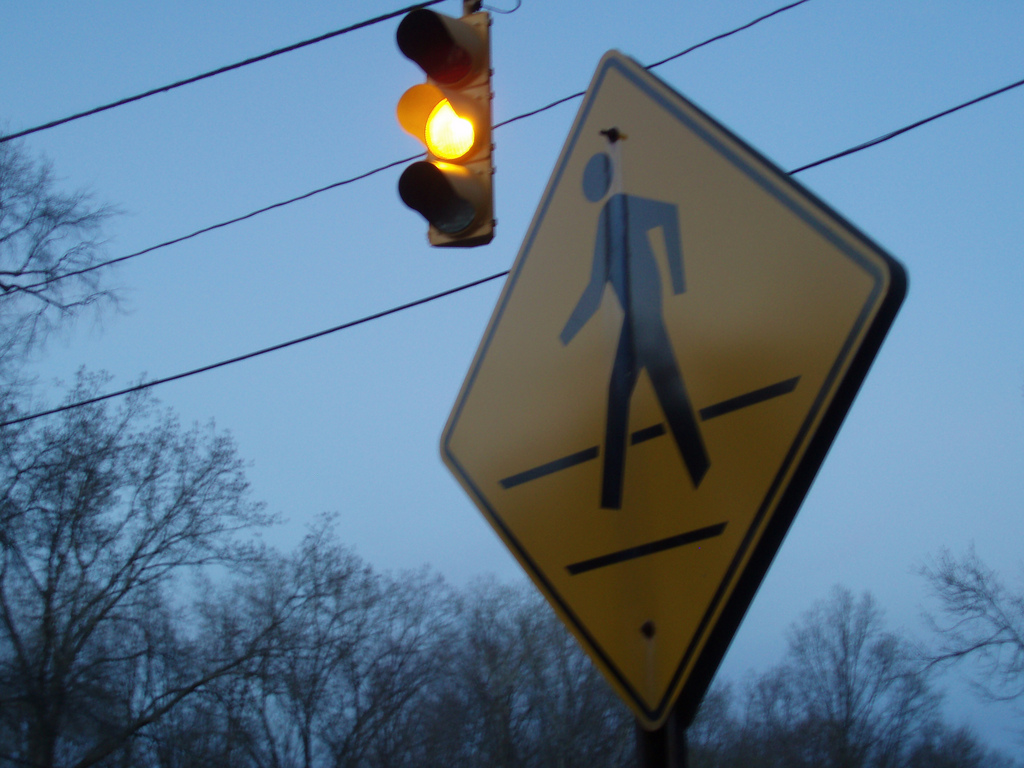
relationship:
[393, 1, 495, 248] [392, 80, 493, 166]
stop light has a traffic light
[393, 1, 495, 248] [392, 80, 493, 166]
traffic signal has a traffic light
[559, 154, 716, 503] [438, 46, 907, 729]
image of person on crossing sign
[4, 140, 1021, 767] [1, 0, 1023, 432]
trees are near power lines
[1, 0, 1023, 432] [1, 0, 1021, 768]
power lines against sky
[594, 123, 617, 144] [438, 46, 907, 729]
bolt holding crossing sign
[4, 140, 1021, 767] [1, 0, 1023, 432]
trees behind power lines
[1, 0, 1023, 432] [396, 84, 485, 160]
power lines behind traffic light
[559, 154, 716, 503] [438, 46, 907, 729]
stick figure ma of crossing sign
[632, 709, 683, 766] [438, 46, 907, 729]
pole holding crossing sign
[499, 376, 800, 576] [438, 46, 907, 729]
lies of crossing sign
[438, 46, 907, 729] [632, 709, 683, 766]
crossing sign of pole